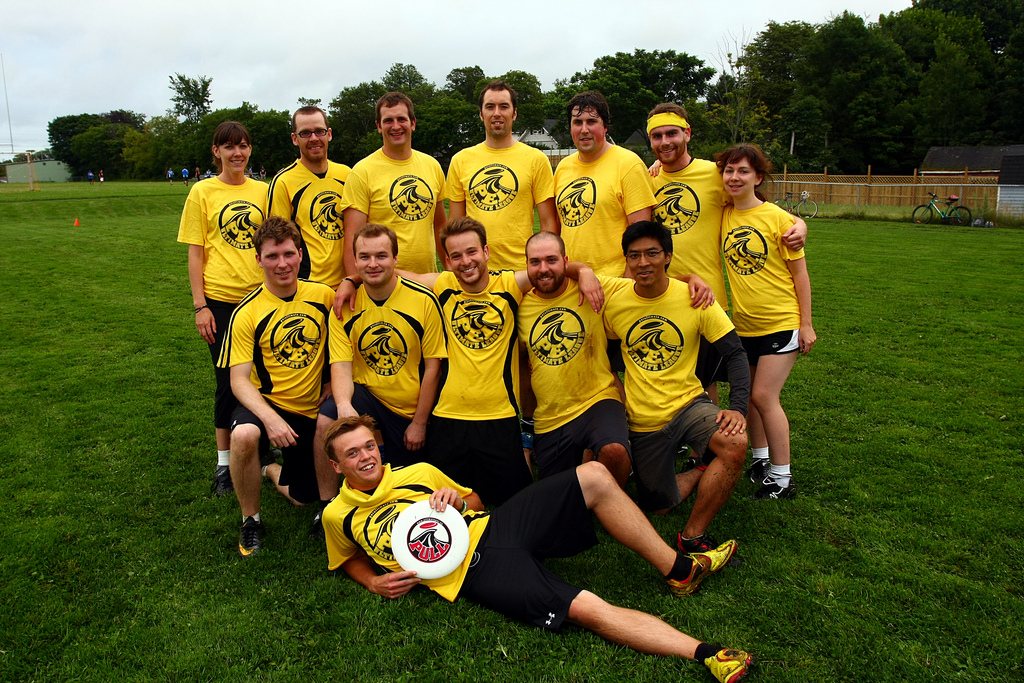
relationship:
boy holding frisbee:
[318, 414, 754, 683] [389, 496, 472, 579]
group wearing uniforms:
[175, 79, 816, 683] [171, 144, 815, 602]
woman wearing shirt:
[174, 118, 277, 495] [176, 175, 272, 305]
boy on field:
[318, 414, 754, 683] [0, 180, 1022, 683]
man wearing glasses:
[264, 108, 353, 296] [293, 125, 327, 140]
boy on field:
[319, 410, 761, 682] [0, 180, 1022, 683]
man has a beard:
[516, 228, 634, 492] [526, 270, 569, 297]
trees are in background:
[46, 9, 1022, 183] [2, 3, 1021, 189]